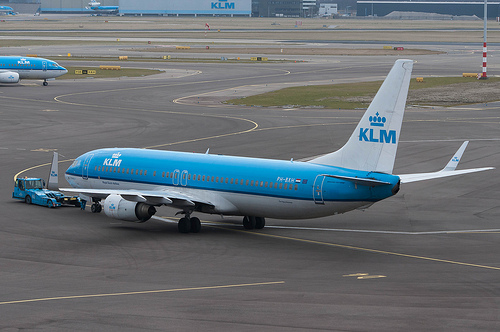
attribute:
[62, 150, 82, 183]
nose — airplane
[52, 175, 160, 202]
wing — airplane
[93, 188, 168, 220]
turbine — airplane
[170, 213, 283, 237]
wheel — airplane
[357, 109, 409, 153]
logo — airplane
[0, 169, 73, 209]
cart — luggage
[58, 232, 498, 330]
runway — airport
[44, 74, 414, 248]
plane — blue , white 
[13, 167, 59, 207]
truck — blue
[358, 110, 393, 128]
logo — blue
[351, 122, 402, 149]
letters — blue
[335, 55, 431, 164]
tail — white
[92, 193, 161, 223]
engine — plane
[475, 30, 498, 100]
pole — striped, red, white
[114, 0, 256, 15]
sign — white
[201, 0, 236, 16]
letters — blue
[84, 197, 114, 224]
wheels — landing, plane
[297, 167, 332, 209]
door — blue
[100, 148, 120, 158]
logo — white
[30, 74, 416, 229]
plane — blue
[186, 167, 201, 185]
window — small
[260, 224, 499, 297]
line — yellow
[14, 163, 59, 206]
car — blue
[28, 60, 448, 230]
plane — one